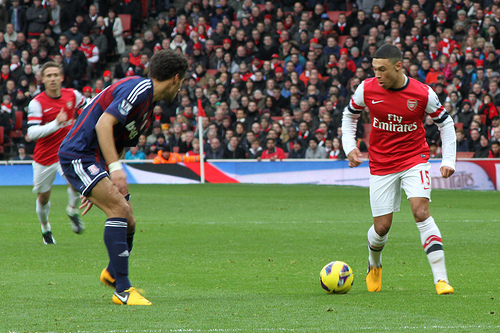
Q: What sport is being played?
A: Soccer.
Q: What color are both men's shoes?
A: Yellow.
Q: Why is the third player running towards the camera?
A: To make a play.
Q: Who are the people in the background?
A: Fans.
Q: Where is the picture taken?
A: A soccer field.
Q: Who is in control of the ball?
A: The man in red.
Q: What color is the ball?
A: Yellow.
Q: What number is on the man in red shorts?
A: 15.